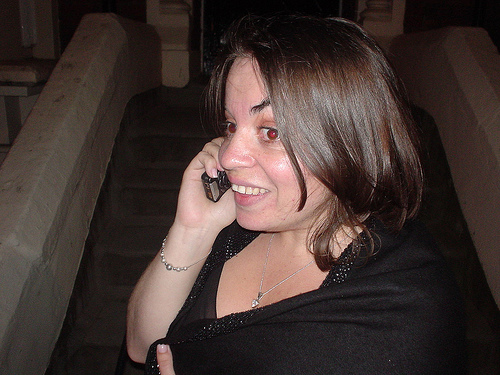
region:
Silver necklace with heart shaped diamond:
[247, 238, 294, 310]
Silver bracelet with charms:
[152, 220, 207, 281]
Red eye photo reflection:
[221, 107, 282, 148]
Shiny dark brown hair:
[305, 37, 404, 175]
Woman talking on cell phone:
[183, 55, 308, 220]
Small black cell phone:
[193, 163, 228, 206]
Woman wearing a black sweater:
[125, 29, 402, 354]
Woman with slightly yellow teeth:
[228, 180, 275, 201]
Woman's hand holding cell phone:
[178, 143, 240, 232]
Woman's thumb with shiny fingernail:
[146, 337, 181, 374]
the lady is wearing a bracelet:
[157, 255, 169, 261]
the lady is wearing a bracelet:
[175, 257, 190, 302]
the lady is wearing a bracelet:
[166, 255, 170, 275]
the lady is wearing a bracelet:
[176, 254, 183, 284]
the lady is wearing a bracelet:
[165, 237, 172, 275]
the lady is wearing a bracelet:
[163, 260, 181, 276]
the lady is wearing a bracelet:
[167, 258, 179, 268]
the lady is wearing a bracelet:
[173, 260, 179, 277]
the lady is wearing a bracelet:
[164, 254, 187, 282]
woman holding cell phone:
[128, 10, 460, 369]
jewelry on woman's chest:
[233, 254, 305, 319]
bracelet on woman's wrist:
[150, 225, 214, 287]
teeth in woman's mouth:
[225, 176, 278, 206]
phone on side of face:
[195, 158, 240, 206]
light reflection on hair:
[278, 62, 396, 136]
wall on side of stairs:
[17, 42, 140, 264]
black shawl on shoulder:
[297, 239, 437, 373]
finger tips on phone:
[200, 155, 226, 184]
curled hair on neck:
[300, 215, 350, 272]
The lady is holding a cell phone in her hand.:
[168, 126, 242, 245]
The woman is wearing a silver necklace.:
[246, 248, 323, 309]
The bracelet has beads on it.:
[142, 231, 216, 286]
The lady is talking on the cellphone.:
[185, 160, 280, 205]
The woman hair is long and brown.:
[290, 59, 437, 237]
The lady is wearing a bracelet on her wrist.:
[153, 236, 215, 278]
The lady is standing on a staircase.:
[66, 38, 246, 374]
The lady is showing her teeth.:
[211, 165, 295, 219]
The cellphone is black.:
[185, 162, 241, 203]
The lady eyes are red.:
[219, 106, 336, 148]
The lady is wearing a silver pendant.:
[246, 238, 296, 300]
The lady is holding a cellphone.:
[193, 160, 228, 215]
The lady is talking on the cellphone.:
[193, 77, 348, 231]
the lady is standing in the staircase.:
[83, 44, 218, 330]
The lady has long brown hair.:
[270, 26, 429, 198]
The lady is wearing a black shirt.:
[188, 287, 434, 369]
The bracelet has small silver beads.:
[130, 229, 202, 279]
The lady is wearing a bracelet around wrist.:
[153, 232, 209, 289]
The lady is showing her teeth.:
[222, 169, 290, 202]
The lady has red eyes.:
[219, 101, 307, 148]